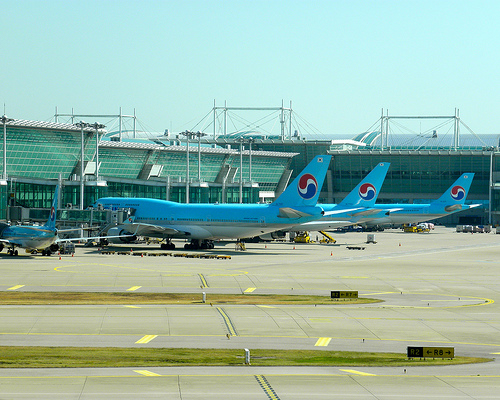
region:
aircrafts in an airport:
[4, 143, 489, 260]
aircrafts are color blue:
[20, 143, 491, 271]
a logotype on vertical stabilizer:
[281, 145, 333, 205]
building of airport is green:
[3, 105, 482, 205]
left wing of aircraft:
[120, 216, 207, 250]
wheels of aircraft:
[145, 235, 222, 252]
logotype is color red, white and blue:
[285, 165, 321, 200]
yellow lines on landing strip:
[1, 260, 468, 385]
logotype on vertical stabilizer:
[434, 160, 478, 202]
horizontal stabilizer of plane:
[10, 220, 100, 235]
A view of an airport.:
[15, 15, 489, 349]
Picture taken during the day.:
[19, 13, 486, 362]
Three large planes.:
[69, 145, 480, 252]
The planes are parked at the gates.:
[58, 131, 491, 256]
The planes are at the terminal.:
[48, 113, 497, 236]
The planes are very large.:
[56, 103, 497, 291]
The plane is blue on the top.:
[96, 188, 273, 226]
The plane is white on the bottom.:
[208, 228, 244, 238]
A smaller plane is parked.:
[1, 160, 116, 278]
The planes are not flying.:
[86, 128, 490, 245]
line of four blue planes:
[3, 155, 495, 251]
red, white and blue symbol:
[296, 172, 319, 201]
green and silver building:
[1, 95, 498, 232]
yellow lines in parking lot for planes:
[3, 255, 498, 387]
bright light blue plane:
[91, 155, 372, 242]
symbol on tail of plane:
[448, 181, 465, 201]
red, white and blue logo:
[296, 170, 318, 198]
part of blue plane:
[0, 168, 100, 259]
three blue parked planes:
[93, 150, 484, 242]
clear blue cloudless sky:
[3, 0, 498, 109]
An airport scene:
[3, 2, 493, 396]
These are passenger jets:
[3, 151, 491, 261]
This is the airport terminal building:
[0, 111, 497, 247]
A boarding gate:
[4, 195, 144, 231]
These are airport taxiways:
[0, 260, 495, 398]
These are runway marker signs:
[324, 283, 456, 363]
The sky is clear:
[1, 5, 497, 102]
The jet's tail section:
[274, 152, 365, 226]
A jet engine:
[105, 222, 142, 247]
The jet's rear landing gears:
[157, 235, 206, 253]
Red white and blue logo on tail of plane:
[298, 174, 318, 199]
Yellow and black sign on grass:
[405, 343, 455, 358]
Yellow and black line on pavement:
[216, 305, 241, 337]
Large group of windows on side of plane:
[135, 215, 266, 225]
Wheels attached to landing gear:
[160, 241, 176, 248]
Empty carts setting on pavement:
[452, 222, 492, 233]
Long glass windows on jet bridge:
[28, 207, 115, 223]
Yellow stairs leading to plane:
[288, 230, 336, 244]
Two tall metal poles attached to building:
[452, 105, 461, 156]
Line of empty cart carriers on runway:
[99, 248, 233, 260]